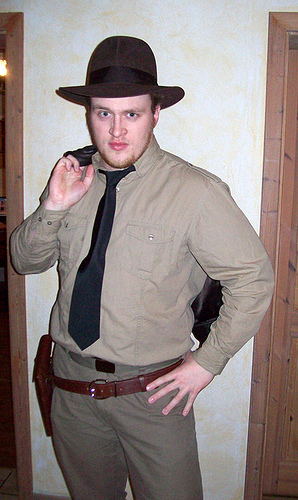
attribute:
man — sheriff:
[9, 35, 275, 498]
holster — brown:
[32, 333, 55, 438]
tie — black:
[67, 165, 136, 351]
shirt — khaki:
[8, 132, 276, 374]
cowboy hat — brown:
[58, 35, 185, 111]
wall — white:
[0, 1, 298, 500]